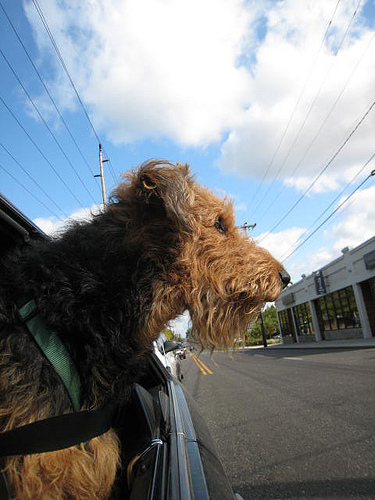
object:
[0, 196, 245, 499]
car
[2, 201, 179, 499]
window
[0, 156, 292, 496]
dog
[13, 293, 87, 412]
collar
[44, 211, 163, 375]
neck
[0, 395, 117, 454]
safety belt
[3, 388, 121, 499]
chest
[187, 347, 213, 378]
lines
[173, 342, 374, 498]
road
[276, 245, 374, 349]
store front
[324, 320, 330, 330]
windows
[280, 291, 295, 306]
sign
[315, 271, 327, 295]
sign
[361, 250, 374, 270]
sign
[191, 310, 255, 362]
wiry fur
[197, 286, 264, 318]
chin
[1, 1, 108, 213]
power lines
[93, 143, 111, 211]
pole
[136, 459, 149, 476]
lock button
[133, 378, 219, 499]
door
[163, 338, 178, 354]
side view mirror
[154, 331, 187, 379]
car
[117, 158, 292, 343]
head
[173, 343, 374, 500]
street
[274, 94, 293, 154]
telephone lines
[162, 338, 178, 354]
rear view mirror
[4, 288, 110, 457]
restraints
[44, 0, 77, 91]
wires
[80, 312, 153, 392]
fur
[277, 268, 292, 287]
nose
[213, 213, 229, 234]
right eye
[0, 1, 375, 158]
sky